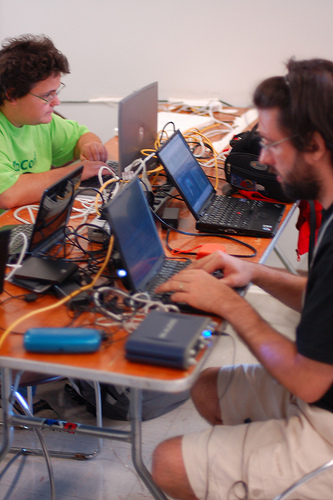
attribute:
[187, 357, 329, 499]
shorts — white, khaki, tan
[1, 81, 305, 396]
table — wooden, wood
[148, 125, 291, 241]
laptop — black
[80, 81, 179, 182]
laptop — silver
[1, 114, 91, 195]
shirt — green, t shirt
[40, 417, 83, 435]
sticker — usa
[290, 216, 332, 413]
shirt — black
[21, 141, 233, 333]
computer cables — white, yellow, black, tangled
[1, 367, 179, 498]
leg — metal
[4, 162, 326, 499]
floor — white, tiled, linoleum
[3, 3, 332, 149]
wall — white, bare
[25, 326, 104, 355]
case — blue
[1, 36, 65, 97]
hair — long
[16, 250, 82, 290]
case — black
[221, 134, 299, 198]
modem — black